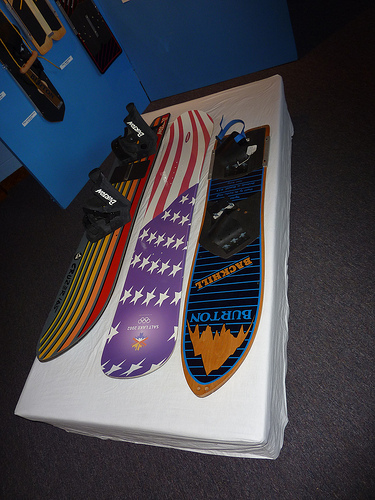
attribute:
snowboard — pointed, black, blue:
[180, 124, 270, 399]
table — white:
[15, 74, 296, 462]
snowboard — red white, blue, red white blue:
[101, 110, 215, 384]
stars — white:
[100, 195, 197, 378]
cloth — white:
[13, 74, 294, 461]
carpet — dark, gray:
[0, 0, 374, 499]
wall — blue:
[0, 1, 299, 209]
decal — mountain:
[184, 320, 255, 374]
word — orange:
[196, 255, 252, 293]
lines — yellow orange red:
[36, 113, 170, 364]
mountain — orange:
[187, 322, 253, 373]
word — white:
[96, 189, 116, 208]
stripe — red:
[74, 116, 162, 343]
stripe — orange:
[55, 115, 164, 353]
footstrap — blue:
[216, 116, 251, 148]